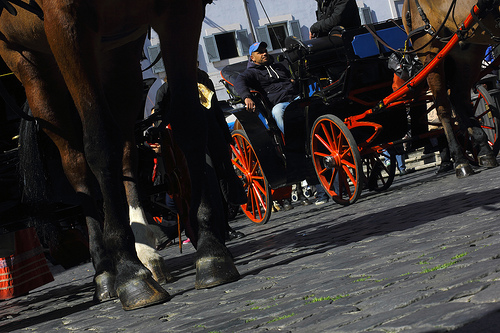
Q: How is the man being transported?
A: Carriage.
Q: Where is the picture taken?
A: Pavement.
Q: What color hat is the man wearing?
A: Blue.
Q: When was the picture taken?
A: Daytime.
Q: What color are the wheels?
A: Red.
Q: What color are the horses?
A: Brown.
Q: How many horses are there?
A: Two.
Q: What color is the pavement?
A: Gray.